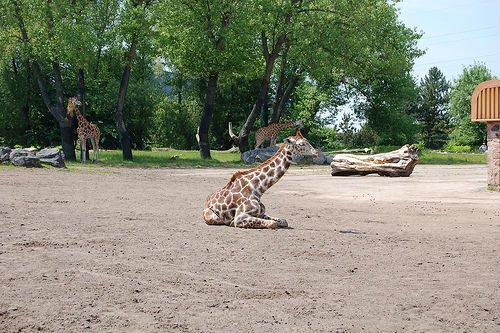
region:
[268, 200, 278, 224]
part of a giraffe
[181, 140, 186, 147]
part of a field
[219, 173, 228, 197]
part of a giraffe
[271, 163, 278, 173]
part of a neck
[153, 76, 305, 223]
a giraffe in ground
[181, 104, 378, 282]
a giraffe sitting in sand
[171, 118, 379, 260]
a giraffe sitting in ground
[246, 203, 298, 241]
legs of the giraffe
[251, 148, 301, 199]
neck of the giraffe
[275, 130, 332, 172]
face of the giraffe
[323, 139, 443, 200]
a wood on the back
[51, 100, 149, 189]
a giraffe near trees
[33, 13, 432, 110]
a clear view of trees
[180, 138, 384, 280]
this is a giraffe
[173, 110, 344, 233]
the neck is long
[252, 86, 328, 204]
this is a head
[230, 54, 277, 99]
this is an old tree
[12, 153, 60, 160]
this is a large rock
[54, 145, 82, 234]
the rock is gray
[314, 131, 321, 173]
this is a nose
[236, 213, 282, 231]
this is a leg of a girraffe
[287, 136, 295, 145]
this is an ear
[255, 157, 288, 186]
this is a neck of a girraffe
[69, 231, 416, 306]
this is a ground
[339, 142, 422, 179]
this is a big log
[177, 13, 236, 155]
this is a tree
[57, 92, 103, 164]
this is a girraffe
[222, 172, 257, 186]
this is a hump of a girraffe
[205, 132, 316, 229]
a giraffe laying on dirt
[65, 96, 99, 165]
a giraffe is standing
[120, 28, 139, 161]
the trunk of a tree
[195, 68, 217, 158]
the trunk of a tree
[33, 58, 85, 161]
the trunk of a tree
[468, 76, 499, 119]
metal roof on a building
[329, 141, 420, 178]
a long on the dirt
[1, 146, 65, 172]
three large stones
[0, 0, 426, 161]
tall flowering trees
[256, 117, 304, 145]
a giraffe is standing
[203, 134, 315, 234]
a giraffe is sitting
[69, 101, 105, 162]
a giraffe is standing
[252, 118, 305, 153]
a giraffe is standing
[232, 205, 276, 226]
leg of a giraffe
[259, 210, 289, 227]
leg of a giraffe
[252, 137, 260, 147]
leg of a giraffe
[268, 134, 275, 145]
leg of a giraffe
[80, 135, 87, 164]
leg of a giraffe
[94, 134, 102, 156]
leg of a giraffe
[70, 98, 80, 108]
head of a giraffe